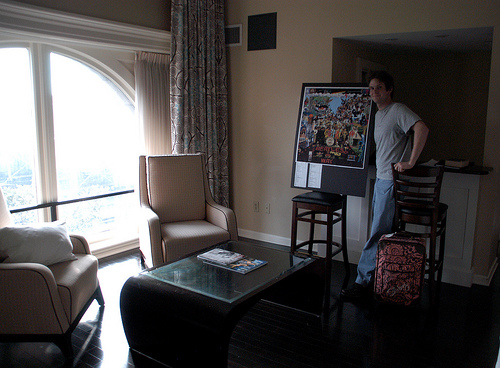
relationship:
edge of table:
[224, 255, 325, 310] [122, 237, 328, 367]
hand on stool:
[394, 160, 414, 171] [390, 162, 448, 293]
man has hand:
[339, 67, 428, 300] [394, 160, 414, 171]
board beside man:
[290, 83, 373, 196] [339, 67, 428, 300]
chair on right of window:
[138, 151, 239, 271] [0, 44, 140, 245]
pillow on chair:
[0, 219, 76, 267] [0, 188, 104, 367]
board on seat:
[290, 83, 373, 196] [292, 191, 344, 208]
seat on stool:
[292, 191, 344, 208] [290, 190, 350, 315]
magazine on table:
[196, 246, 245, 267] [122, 237, 328, 367]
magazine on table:
[203, 254, 268, 273] [122, 237, 328, 367]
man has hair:
[339, 67, 428, 300] [365, 69, 396, 99]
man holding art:
[339, 67, 428, 300] [290, 83, 373, 196]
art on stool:
[290, 83, 373, 196] [290, 190, 350, 315]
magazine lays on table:
[196, 246, 245, 267] [122, 237, 328, 367]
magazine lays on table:
[203, 254, 268, 273] [122, 237, 328, 367]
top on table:
[138, 239, 312, 302] [122, 237, 328, 367]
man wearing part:
[339, 67, 428, 300] [371, 101, 423, 180]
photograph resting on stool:
[290, 83, 373, 196] [290, 190, 350, 315]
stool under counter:
[390, 162, 448, 293] [370, 151, 492, 175]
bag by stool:
[372, 231, 426, 312] [390, 162, 448, 293]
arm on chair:
[205, 200, 237, 232] [138, 151, 239, 271]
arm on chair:
[138, 204, 163, 242] [138, 151, 239, 271]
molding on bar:
[370, 179, 471, 260] [362, 152, 494, 288]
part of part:
[371, 101, 423, 180] [371, 101, 423, 180]